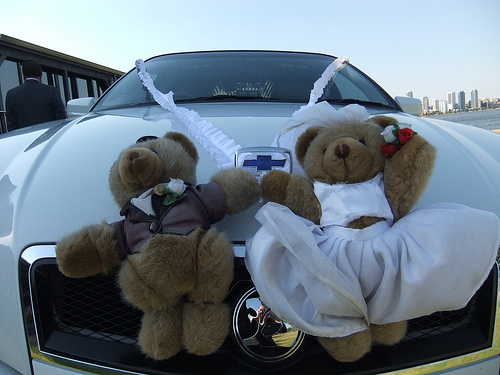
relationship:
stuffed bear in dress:
[254, 113, 437, 362] [241, 169, 499, 341]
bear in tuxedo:
[73, 101, 279, 323] [105, 177, 226, 261]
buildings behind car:
[421, 89, 489, 113] [0, 50, 497, 371]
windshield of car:
[91, 49, 403, 109] [0, 50, 497, 371]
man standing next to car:
[3, 56, 64, 129] [210, 105, 284, 139]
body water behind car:
[421, 96, 498, 136] [0, 50, 497, 371]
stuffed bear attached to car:
[259, 115, 437, 362] [0, 49, 500, 375]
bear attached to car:
[56, 131, 262, 360] [0, 49, 500, 375]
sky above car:
[2, 0, 499, 50] [0, 50, 497, 371]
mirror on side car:
[400, 93, 424, 118] [0, 50, 497, 371]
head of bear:
[107, 130, 198, 203] [52, 130, 258, 357]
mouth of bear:
[117, 147, 154, 187] [56, 131, 262, 360]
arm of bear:
[53, 212, 128, 274] [52, 130, 258, 357]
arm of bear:
[195, 168, 263, 216] [52, 130, 258, 357]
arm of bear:
[263, 169, 323, 225] [260, 115, 435, 360]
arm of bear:
[385, 129, 436, 214] [260, 115, 435, 360]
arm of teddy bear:
[270, 169, 297, 208] [246, 116, 495, 358]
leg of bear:
[181, 235, 234, 356] [56, 131, 262, 360]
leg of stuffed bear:
[319, 326, 373, 364] [259, 115, 437, 362]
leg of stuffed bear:
[370, 319, 409, 343] [259, 115, 437, 362]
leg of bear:
[183, 282, 229, 353] [52, 130, 258, 357]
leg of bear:
[129, 294, 182, 360] [52, 130, 258, 357]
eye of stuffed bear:
[314, 136, 331, 160] [259, 115, 437, 362]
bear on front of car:
[56, 131, 262, 360] [0, 50, 497, 371]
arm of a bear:
[195, 174, 260, 218] [52, 130, 258, 357]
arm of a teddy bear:
[377, 129, 437, 209] [264, 110, 464, 359]